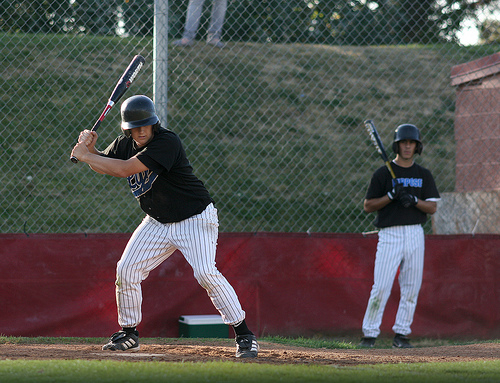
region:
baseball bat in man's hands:
[69, 52, 149, 164]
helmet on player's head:
[117, 92, 157, 137]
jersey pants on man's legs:
[361, 223, 433, 337]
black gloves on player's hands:
[387, 181, 414, 209]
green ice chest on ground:
[177, 314, 228, 337]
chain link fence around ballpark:
[1, 0, 498, 240]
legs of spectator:
[172, 0, 229, 49]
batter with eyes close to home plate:
[70, 94, 253, 357]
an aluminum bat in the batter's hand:
[69, 53, 147, 165]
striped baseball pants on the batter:
[112, 201, 245, 327]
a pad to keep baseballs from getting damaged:
[2, 230, 498, 336]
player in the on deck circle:
[359, 124, 440, 345]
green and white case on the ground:
[176, 313, 234, 336]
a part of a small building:
[451, 53, 498, 235]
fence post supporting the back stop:
[152, 24, 170, 127]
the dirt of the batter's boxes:
[0, 338, 369, 365]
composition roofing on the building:
[451, 53, 498, 80]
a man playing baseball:
[46, 33, 331, 381]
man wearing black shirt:
[62, 95, 231, 237]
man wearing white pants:
[86, 191, 261, 360]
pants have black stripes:
[97, 179, 272, 351]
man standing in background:
[305, 76, 474, 360]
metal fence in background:
[5, 8, 495, 347]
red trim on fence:
[8, 190, 499, 355]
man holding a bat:
[57, 46, 222, 220]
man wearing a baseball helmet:
[93, 86, 176, 141]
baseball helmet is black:
[113, 79, 176, 139]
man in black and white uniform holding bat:
[83, 82, 237, 339]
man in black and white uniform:
[360, 108, 435, 350]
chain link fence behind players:
[209, 12, 343, 194]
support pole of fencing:
[143, 16, 177, 114]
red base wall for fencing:
[34, 211, 449, 331]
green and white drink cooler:
[180, 285, 249, 348]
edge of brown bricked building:
[416, 63, 498, 205]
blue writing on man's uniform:
[398, 171, 428, 196]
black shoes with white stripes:
[90, 300, 267, 360]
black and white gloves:
[382, 173, 422, 213]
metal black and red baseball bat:
[70, 53, 145, 168]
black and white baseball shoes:
[100, 325, 262, 359]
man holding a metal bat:
[358, 113, 438, 355]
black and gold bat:
[362, 117, 410, 204]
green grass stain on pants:
[367, 289, 382, 314]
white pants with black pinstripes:
[112, 203, 246, 335]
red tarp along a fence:
[2, 224, 499, 344]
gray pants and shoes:
[170, 0, 234, 51]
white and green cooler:
[176, 309, 231, 339]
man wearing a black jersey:
[70, 93, 260, 358]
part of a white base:
[92, 349, 166, 360]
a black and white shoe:
[233, 335, 262, 357]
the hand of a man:
[68, 145, 90, 161]